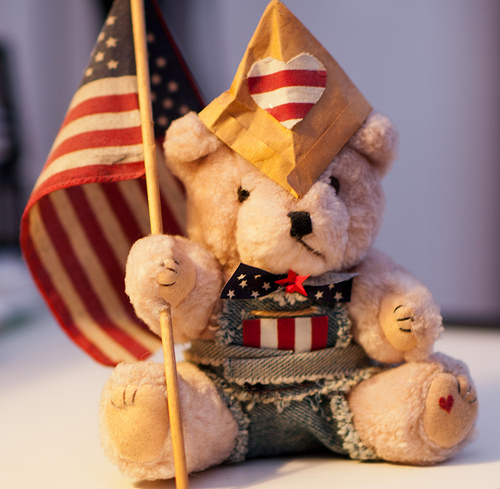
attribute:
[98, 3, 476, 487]
teddy bear — stuffed, foor, small, denim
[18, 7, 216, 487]
flag — american, mini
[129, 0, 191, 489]
stick — wooden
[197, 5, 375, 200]
hat — small, military-style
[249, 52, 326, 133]
striped heart — red, white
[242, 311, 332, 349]
stripe design — red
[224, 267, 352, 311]
bowtie — red, blue, stripe, navy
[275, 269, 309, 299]
star — red, shiny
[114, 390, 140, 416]
stitching — black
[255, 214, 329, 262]
stitching — black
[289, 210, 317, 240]
nose — black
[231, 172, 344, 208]
stitching — black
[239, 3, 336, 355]
colors — american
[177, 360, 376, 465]
shorts — denim